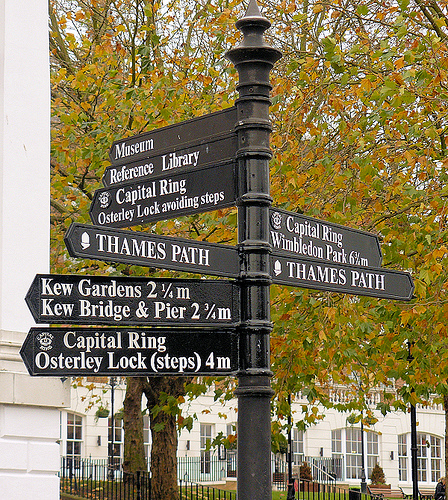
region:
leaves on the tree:
[385, 328, 445, 380]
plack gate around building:
[65, 460, 132, 496]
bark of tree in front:
[149, 414, 185, 497]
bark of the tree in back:
[125, 381, 151, 469]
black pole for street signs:
[226, 0, 277, 498]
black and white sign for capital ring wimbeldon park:
[272, 213, 384, 264]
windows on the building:
[332, 425, 380, 475]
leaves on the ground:
[86, 483, 109, 498]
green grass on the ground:
[217, 486, 233, 498]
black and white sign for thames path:
[85, 223, 235, 274]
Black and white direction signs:
[25, 109, 435, 406]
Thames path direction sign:
[282, 248, 416, 312]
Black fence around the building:
[63, 435, 392, 497]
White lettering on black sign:
[74, 226, 225, 268]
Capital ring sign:
[30, 320, 235, 376]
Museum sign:
[108, 134, 173, 159]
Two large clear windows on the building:
[319, 418, 447, 499]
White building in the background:
[54, 264, 446, 498]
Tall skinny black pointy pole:
[211, 3, 285, 496]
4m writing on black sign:
[203, 351, 233, 372]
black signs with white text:
[17, 114, 418, 381]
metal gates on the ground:
[47, 442, 397, 496]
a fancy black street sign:
[22, 3, 418, 497]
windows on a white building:
[393, 429, 442, 484]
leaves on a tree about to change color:
[48, 4, 446, 437]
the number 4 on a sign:
[205, 351, 216, 372]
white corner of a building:
[0, 4, 69, 494]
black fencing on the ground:
[53, 451, 394, 497]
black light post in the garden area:
[407, 342, 423, 492]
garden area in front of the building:
[60, 461, 432, 498]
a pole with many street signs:
[24, 109, 414, 375]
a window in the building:
[198, 430, 212, 478]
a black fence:
[68, 456, 215, 498]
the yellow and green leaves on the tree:
[303, 136, 442, 196]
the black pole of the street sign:
[233, 14, 279, 494]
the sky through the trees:
[58, 7, 208, 83]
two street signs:
[272, 209, 414, 302]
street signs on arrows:
[22, 103, 240, 378]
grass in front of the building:
[272, 484, 350, 498]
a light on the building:
[389, 450, 396, 461]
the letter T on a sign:
[93, 231, 107, 254]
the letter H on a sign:
[105, 232, 120, 253]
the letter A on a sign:
[117, 235, 131, 256]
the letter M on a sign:
[129, 238, 146, 256]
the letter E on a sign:
[146, 239, 156, 261]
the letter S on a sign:
[155, 242, 169, 259]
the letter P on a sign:
[171, 243, 179, 259]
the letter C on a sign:
[112, 186, 125, 206]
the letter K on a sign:
[40, 276, 55, 297]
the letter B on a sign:
[79, 297, 92, 318]